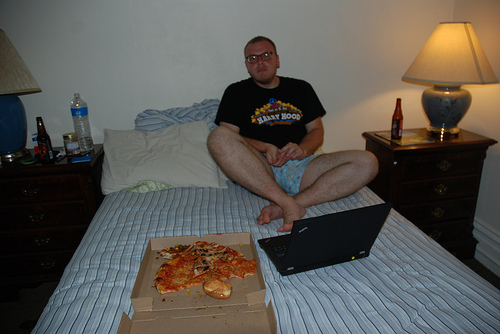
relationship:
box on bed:
[132, 231, 274, 333] [33, 110, 499, 331]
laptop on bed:
[258, 195, 390, 286] [33, 110, 499, 331]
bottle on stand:
[36, 117, 55, 162] [5, 134, 101, 298]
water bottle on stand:
[69, 94, 95, 152] [5, 134, 101, 298]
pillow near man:
[99, 128, 224, 189] [209, 33, 384, 235]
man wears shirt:
[209, 33, 384, 235] [214, 78, 331, 151]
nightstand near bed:
[371, 131, 496, 264] [33, 110, 499, 331]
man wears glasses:
[209, 33, 384, 235] [247, 48, 280, 65]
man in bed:
[209, 33, 384, 235] [33, 110, 499, 331]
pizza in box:
[152, 240, 250, 307] [132, 231, 274, 333]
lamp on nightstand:
[402, 21, 495, 134] [371, 131, 496, 264]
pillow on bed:
[99, 128, 224, 189] [33, 110, 499, 331]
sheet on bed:
[102, 184, 246, 231] [33, 110, 499, 331]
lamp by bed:
[402, 21, 495, 134] [33, 110, 499, 331]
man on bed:
[209, 33, 384, 235] [33, 110, 499, 331]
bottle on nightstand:
[390, 98, 404, 141] [371, 131, 496, 264]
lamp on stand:
[2, 36, 42, 155] [5, 134, 101, 298]